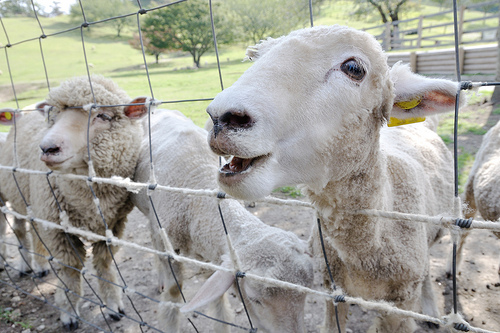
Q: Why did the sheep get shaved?
A: To get the wool to make projects.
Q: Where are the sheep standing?
A: On a dirt patch.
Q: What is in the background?
A: Trees.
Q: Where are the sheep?
A: Behind the fence.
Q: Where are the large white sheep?
A: In a pen.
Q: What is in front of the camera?
A: The sheep's face.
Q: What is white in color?
A: The sheep.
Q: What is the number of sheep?
A: Three.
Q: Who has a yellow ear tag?
A: The sheep.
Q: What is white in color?
A: The sheep.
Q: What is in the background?
A: Trees.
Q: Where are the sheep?
A: Behind the fence.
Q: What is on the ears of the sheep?
A: Yellow tags.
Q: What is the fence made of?
A: Wire.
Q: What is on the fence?
A: Sheep wool.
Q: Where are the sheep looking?
A: At the camera.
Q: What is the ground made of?
A: Grass.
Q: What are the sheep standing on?
A: Dirt.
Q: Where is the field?
A: Behind the sheep.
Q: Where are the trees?
A: The back of the field.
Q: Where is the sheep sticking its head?
A: Through the fence.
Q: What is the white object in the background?
A: Fence.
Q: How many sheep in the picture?
A: 4.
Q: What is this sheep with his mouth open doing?
A: Posing.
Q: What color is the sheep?
A: White.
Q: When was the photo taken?
A: Daytime.